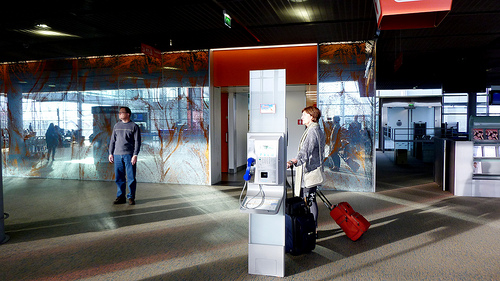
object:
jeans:
[104, 154, 141, 202]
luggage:
[323, 201, 373, 243]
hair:
[297, 103, 326, 124]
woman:
[274, 101, 337, 259]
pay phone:
[231, 129, 286, 220]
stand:
[236, 61, 300, 278]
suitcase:
[276, 194, 329, 259]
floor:
[0, 181, 497, 280]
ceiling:
[1, 1, 499, 81]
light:
[14, 19, 85, 47]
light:
[264, 2, 343, 29]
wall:
[0, 39, 379, 192]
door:
[213, 88, 234, 181]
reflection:
[313, 104, 375, 190]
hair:
[111, 106, 134, 118]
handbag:
[292, 127, 325, 190]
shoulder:
[300, 120, 326, 149]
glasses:
[112, 110, 131, 116]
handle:
[279, 160, 300, 206]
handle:
[309, 183, 337, 211]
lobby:
[0, 0, 492, 281]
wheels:
[354, 235, 368, 243]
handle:
[240, 153, 261, 184]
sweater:
[289, 125, 333, 189]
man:
[90, 105, 154, 206]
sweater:
[100, 120, 149, 160]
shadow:
[0, 196, 251, 246]